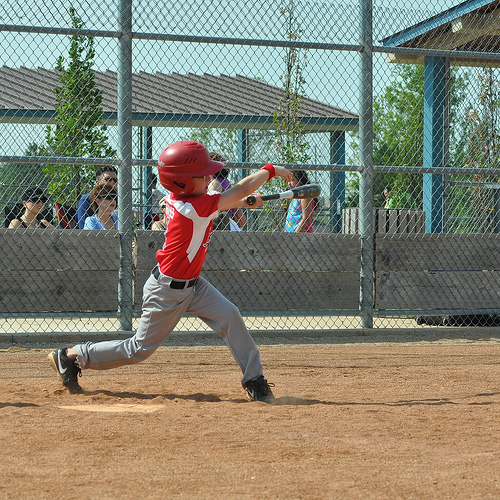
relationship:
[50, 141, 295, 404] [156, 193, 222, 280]
boy has shirt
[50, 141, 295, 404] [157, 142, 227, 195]
boy wears helmet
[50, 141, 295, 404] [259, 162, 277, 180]
boy wears bracelet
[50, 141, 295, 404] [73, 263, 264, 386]
boy wears pants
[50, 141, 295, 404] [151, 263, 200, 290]
boy wears belt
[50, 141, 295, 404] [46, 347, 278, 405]
boy wears shoes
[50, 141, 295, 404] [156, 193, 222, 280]
boy wears shirt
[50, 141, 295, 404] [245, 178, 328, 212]
boy hitting baseball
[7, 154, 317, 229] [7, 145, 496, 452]
people watching game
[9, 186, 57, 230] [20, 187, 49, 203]
woman wears visor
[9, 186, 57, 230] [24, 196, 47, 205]
woman wears sunglasses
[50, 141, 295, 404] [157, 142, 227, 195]
child wears helmet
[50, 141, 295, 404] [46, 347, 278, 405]
child wears sneakers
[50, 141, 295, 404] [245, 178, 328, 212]
boy hitting ball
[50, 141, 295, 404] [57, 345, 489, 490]
boy stands in dirt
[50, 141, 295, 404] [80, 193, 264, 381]
boy wears uniform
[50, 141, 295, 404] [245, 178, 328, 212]
boy playing baseball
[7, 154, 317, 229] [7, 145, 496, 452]
adults watching baseball game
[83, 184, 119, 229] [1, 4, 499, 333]
person sits behind fence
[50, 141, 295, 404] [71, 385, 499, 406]
boy has shadow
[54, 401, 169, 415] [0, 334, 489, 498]
home plate on baseball field